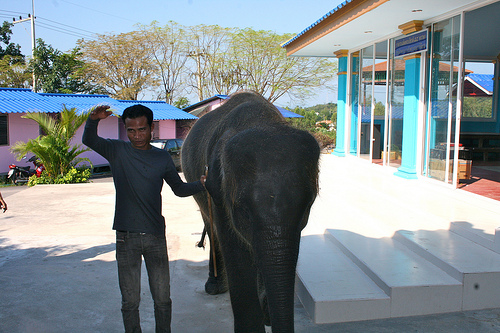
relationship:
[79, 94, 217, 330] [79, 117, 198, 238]
man wearing shirt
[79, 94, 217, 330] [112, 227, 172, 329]
man wearing jeans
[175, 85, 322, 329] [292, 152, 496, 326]
elephant near stairs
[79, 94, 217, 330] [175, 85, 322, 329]
man stands near elephant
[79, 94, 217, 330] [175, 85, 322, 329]
man touches elephant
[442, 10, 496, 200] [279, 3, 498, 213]
windows on building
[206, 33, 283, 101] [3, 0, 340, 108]
trees in distance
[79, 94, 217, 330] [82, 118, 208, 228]
man wearing shirt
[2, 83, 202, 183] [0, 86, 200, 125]
building has roof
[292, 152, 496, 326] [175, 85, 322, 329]
stairs next to elephant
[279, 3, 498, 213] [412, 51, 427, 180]
building has trim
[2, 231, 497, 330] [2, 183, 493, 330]
shadow on pavement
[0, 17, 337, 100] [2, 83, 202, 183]
trees behind building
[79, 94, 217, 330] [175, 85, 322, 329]
man next to elephant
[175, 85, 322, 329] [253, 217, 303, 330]
elephant has trunk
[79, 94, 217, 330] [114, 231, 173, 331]
man wearing jeans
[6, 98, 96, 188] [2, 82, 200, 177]
plant in front of house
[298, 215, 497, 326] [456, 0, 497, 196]
stairs leading to door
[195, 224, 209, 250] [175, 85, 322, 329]
tail on elephant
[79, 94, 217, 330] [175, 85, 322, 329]
man standing next to elephant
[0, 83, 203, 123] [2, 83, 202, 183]
roof on building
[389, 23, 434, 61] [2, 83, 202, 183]
sign on building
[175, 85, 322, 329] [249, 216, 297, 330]
elephant has trunk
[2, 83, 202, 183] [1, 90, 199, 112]
building has roof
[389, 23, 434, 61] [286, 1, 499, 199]
sign on building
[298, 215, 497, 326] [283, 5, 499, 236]
stairs are leading to building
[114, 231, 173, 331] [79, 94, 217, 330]
jeans on man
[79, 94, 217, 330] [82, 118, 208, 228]
man in a shirt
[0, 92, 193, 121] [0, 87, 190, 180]
awning of a building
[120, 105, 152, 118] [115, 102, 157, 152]
hair on a head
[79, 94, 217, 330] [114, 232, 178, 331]
man wearing blue jeans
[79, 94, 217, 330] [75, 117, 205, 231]
man wearing shirt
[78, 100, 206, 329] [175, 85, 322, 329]
person next to elephant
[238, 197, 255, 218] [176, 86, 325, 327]
eye of animal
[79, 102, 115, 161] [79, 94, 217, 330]
arm/hand of man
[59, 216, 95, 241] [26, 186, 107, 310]
light on ground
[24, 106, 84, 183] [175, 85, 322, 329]
tree near elephant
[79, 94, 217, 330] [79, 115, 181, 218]
man with a shirt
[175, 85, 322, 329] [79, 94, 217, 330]
elephant with a man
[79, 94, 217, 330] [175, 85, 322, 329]
man with an elephant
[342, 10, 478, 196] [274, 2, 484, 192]
front of a building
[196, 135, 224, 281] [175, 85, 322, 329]
strap to hold onto an elephant